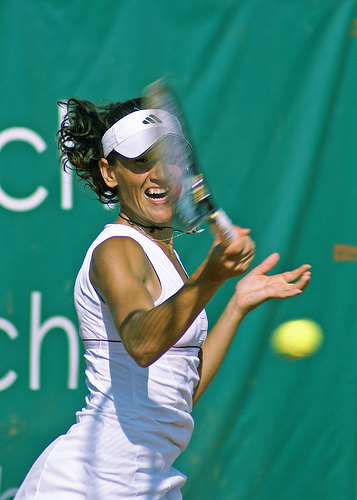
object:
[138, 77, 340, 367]
player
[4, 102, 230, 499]
player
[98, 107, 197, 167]
cap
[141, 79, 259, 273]
woman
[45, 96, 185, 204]
hair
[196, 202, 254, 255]
handle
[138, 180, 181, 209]
mouth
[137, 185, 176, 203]
teeth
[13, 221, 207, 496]
dress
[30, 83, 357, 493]
woman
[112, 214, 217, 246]
necklace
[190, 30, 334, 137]
wall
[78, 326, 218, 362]
stripe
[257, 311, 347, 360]
air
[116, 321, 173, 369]
elbow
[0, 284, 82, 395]
letters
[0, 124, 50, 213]
c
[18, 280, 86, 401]
h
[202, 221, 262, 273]
hand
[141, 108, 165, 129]
design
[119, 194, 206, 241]
woman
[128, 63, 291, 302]
racket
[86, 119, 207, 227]
player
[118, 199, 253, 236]
pendant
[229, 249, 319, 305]
hand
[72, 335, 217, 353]
dress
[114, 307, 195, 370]
shadow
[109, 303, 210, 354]
racket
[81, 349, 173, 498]
shadow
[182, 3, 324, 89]
background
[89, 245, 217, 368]
arm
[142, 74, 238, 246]
racket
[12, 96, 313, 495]
woman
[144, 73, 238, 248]
racquet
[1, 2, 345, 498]
board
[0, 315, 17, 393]
letter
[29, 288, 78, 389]
letter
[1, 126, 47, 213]
letter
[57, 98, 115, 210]
letter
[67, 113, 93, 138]
curl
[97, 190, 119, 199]
curl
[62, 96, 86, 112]
curl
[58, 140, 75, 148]
curl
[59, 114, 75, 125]
curl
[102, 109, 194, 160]
visor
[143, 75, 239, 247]
tennis racket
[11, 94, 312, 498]
player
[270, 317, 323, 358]
ball